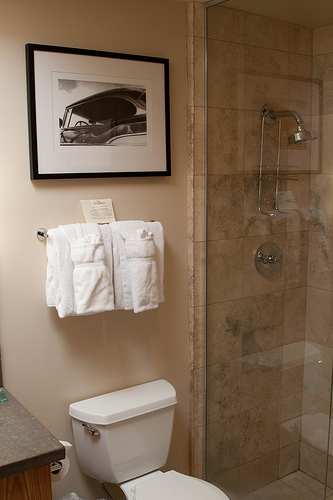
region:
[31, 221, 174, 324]
white towels hanging on a bar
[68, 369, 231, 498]
white toilet bowl on ground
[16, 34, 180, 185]
framed picture on bathroom wall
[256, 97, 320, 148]
metal shower fixture in bathroom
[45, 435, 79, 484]
toilet paper on a holder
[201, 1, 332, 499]
glass shower door in a bathroom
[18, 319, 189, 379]
beige walls in a bathroom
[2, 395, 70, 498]
counter and cabinet in a bathroom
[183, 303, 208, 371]
tile in a bathroom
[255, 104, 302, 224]
metal caddy in a shower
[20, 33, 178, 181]
Picture hanging on wall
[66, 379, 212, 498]
White porcelian toilet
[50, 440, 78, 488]
Roll of toilet paper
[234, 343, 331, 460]
Reflection of toilet in shower door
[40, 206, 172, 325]
Four white towels on rack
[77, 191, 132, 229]
White note above towels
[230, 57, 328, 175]
Reflection of picture in shower door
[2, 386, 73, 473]
Black counter top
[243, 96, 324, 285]
Silver plumbing for shower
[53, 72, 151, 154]
Photo of a particial car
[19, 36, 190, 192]
picture with black frame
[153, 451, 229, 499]
toilet with closed cover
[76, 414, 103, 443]
metal handle on tank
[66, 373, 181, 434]
cover of toilet tank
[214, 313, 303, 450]
glass door on shower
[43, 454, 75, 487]
white roll of toilet paper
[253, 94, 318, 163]
metal shower head on wall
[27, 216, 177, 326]
white towels on rack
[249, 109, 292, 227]
rack hanging from shower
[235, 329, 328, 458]
reflection of toilet on glass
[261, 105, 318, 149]
a gray shower head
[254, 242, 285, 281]
a circle shower faucet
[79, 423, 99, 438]
a gray toilet handle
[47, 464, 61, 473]
part of a tissue holder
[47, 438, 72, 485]
a white roll of toilet tissue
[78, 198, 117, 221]
a greeting card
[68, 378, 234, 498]
a white toilet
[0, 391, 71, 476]
part of a sink counter top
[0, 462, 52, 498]
part of a brown sink cabinet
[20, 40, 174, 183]
a black picture frame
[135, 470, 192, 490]
this is a toilet sink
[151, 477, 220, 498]
the sink is covered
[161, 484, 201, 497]
the lid is white in color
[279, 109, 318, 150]
this is a shower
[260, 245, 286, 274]
this is a tap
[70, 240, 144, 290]
this is a towel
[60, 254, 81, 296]
the towel is white in color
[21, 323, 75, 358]
this is the wall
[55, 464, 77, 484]
this is a tissue paper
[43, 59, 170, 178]
this is a picture